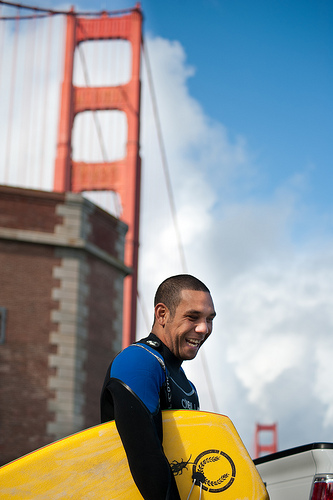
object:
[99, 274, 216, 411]
man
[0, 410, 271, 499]
surfboard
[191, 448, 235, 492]
logo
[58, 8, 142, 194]
bridge support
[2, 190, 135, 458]
wall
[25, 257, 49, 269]
brick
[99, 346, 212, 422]
wetsuit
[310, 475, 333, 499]
tail light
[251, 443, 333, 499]
truck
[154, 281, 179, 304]
hair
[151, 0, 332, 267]
sky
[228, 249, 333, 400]
cloud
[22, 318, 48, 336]
brick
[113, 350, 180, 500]
sleeve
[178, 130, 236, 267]
cloud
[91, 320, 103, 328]
brick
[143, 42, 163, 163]
cable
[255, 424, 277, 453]
bridge support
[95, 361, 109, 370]
brick